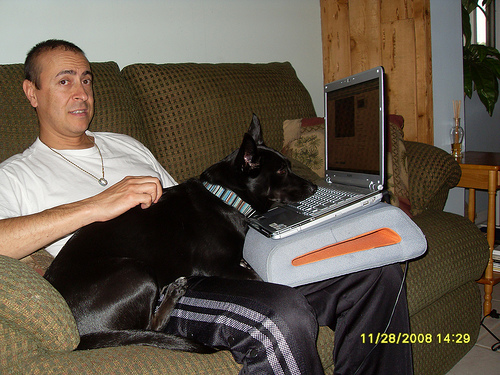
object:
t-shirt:
[2, 131, 180, 258]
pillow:
[0, 250, 81, 356]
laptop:
[247, 64, 390, 241]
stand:
[242, 202, 432, 290]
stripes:
[177, 295, 305, 375]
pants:
[149, 259, 413, 375]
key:
[349, 194, 354, 199]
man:
[0, 37, 416, 373]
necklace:
[37, 131, 111, 188]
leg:
[146, 296, 179, 332]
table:
[459, 150, 499, 316]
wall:
[0, 0, 327, 119]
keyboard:
[286, 186, 359, 216]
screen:
[323, 77, 386, 178]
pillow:
[279, 114, 412, 221]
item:
[445, 97, 467, 165]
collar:
[198, 180, 258, 219]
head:
[229, 109, 323, 217]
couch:
[0, 62, 496, 374]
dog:
[42, 108, 320, 355]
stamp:
[357, 331, 474, 345]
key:
[333, 200, 336, 204]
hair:
[21, 38, 90, 92]